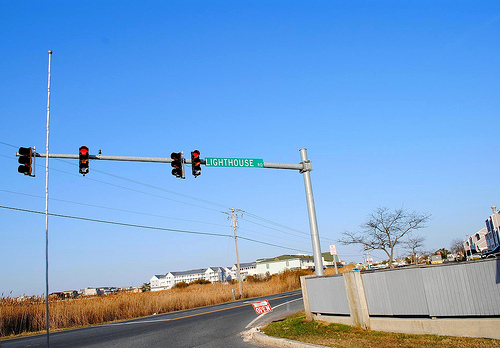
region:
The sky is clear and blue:
[93, 30, 450, 105]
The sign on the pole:
[201, 149, 279, 180]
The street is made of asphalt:
[91, 318, 240, 345]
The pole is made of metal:
[15, 129, 344, 277]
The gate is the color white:
[379, 267, 498, 310]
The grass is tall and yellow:
[46, 288, 212, 318]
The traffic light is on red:
[188, 142, 207, 179]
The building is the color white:
[133, 251, 312, 295]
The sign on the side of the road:
[247, 290, 279, 320]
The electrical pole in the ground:
[218, 198, 251, 300]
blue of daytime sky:
[5, 3, 494, 292]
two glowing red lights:
[76, 146, 203, 157]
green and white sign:
[205, 158, 262, 168]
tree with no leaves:
[342, 207, 422, 262]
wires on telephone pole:
[3, 140, 315, 254]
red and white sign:
[251, 297, 271, 316]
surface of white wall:
[305, 260, 498, 315]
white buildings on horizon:
[153, 252, 333, 288]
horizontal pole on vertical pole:
[23, 147, 321, 274]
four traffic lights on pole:
[17, 145, 202, 178]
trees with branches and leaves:
[353, 206, 416, 256]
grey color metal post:
[296, 148, 331, 265]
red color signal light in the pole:
[15, 144, 216, 176]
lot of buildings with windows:
[138, 263, 245, 287]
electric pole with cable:
[218, 198, 254, 298]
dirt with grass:
[292, 318, 327, 346]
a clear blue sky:
[99, 25, 428, 105]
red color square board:
[247, 297, 277, 316]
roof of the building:
[166, 267, 213, 274]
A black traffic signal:
[158, 142, 186, 178]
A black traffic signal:
[187, 149, 206, 183]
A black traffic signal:
[69, 143, 93, 175]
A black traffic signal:
[15, 139, 34, 178]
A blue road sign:
[201, 153, 268, 178]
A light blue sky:
[400, 85, 497, 194]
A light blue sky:
[290, 25, 429, 106]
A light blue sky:
[142, 32, 314, 113]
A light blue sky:
[6, 0, 114, 80]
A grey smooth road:
[151, 303, 250, 345]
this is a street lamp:
[1, 37, 226, 186]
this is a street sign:
[164, 98, 253, 182]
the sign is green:
[161, 144, 320, 215]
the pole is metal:
[279, 160, 349, 302]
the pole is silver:
[253, 167, 347, 274]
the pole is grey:
[299, 229, 341, 279]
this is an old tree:
[333, 207, 398, 268]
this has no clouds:
[395, 75, 410, 118]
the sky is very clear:
[75, 250, 120, 284]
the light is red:
[43, 127, 130, 169]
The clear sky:
[1, 5, 483, 273]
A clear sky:
[5, 5, 492, 275]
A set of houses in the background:
[139, 245, 339, 285]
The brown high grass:
[6, 259, 351, 328]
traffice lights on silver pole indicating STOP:
[11, 133, 325, 324]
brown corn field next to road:
[6, 267, 331, 336]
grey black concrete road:
[13, 283, 301, 341]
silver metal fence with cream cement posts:
[294, 254, 498, 319]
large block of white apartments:
[143, 250, 317, 299]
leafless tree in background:
[337, 202, 434, 271]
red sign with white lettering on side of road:
[250, 295, 275, 325]